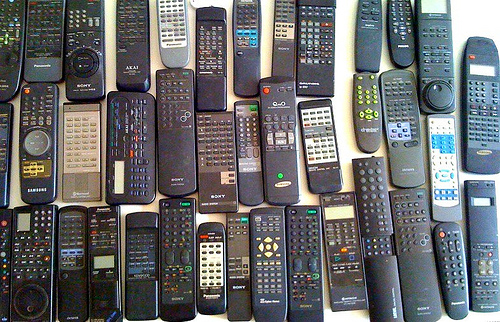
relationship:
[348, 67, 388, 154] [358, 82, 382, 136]
remote has buttons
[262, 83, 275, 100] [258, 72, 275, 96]
button in corner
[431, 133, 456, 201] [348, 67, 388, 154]
areas on remote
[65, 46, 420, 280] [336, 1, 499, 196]
remote controls on table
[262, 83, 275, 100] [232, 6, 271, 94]
button on remote control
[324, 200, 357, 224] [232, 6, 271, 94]
screen on remote control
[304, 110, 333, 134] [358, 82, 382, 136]
white under buttons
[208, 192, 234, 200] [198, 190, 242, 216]
logo on bottom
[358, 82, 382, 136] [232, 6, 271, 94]
buttons on remote control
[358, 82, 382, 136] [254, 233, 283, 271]
buttons in middle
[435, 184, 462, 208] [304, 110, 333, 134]
block under white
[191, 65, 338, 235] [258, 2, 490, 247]
remote controls on a surface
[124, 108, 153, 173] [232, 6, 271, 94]
keypads of remote control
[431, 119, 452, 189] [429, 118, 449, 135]
key pads on white surface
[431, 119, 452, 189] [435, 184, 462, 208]
key pads on blue surface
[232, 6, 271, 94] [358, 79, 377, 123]
remote control with keys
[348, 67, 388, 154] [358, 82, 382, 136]
remote with buttons